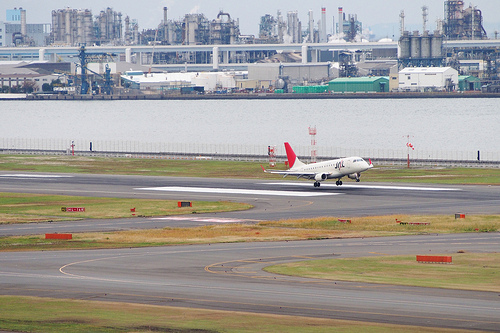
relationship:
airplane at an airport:
[260, 142, 375, 187] [2, 148, 484, 330]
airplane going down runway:
[260, 142, 375, 187] [0, 169, 484, 212]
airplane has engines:
[260, 142, 375, 187] [313, 170, 334, 183]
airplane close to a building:
[260, 142, 375, 187] [0, 0, 500, 94]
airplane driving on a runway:
[259, 141, 376, 189] [1, 165, 484, 215]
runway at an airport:
[0, 169, 484, 212] [2, 148, 484, 330]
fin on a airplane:
[281, 138, 305, 170] [260, 142, 375, 187]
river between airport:
[4, 96, 484, 160] [2, 148, 484, 330]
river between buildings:
[4, 96, 484, 160] [2, 0, 482, 99]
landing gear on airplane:
[314, 181, 342, 187] [260, 142, 375, 187]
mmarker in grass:
[416, 253, 452, 265] [77, 311, 109, 322]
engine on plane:
[315, 166, 335, 182] [270, 150, 381, 195]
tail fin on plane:
[280, 137, 303, 170] [255, 137, 378, 190]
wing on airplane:
[260, 166, 341, 178] [260, 142, 375, 187]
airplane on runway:
[260, 142, 375, 187] [1, 165, 484, 215]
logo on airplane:
[329, 156, 349, 176] [260, 142, 375, 187]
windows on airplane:
[353, 159, 363, 162] [260, 142, 375, 187]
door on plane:
[334, 160, 346, 175] [255, 137, 378, 190]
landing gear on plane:
[309, 173, 348, 194] [272, 138, 376, 192]